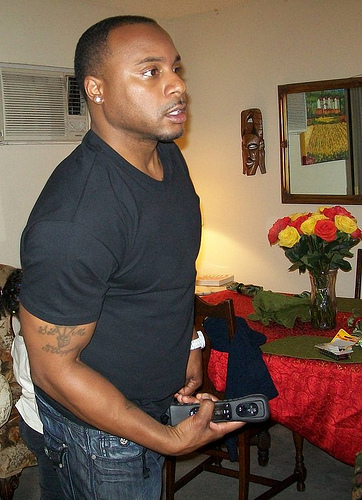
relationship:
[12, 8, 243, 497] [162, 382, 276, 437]
man holding wii remote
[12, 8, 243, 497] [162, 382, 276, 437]
man holding black wii remote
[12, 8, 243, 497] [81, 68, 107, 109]
man wearing earring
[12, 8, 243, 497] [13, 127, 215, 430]
man wearing shirt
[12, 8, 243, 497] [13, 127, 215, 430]
man wearing black shirt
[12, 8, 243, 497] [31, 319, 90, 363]
man with tatto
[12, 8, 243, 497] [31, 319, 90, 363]
man with tattoo on  arm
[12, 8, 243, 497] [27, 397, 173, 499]
man wearing jeans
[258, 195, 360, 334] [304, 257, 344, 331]
flowers in vase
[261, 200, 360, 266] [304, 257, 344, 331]
roses in glass vase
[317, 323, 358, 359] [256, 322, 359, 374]
batteries on green placema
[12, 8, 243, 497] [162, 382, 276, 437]
man playing wii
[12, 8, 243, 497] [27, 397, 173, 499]
man wearing denim jeans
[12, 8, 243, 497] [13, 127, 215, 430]
man wearing black tshirt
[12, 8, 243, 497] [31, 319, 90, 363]
man with tattoo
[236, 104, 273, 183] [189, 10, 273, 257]
mask on wall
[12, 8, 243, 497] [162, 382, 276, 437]
man holds remote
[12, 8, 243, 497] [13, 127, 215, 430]
man wears black shirt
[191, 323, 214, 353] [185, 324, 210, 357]
watch on wrist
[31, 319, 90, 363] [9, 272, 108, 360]
tattoo on bicep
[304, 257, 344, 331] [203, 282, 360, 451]
vase on table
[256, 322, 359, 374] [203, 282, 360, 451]
mat on table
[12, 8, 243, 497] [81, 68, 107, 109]
man has earing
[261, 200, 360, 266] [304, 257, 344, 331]
flowers are in vase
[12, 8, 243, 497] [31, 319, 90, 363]
man has tatto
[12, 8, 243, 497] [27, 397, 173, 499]
man has jeans on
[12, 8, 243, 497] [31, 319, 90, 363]
man has tattoo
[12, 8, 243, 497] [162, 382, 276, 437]
man playing video games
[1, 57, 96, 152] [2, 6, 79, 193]
conditioner unit in wall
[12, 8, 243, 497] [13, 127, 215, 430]
man wearing black t-shirt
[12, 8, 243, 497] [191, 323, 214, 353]
man wearing wristwatch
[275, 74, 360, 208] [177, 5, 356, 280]
mirror hanging on wall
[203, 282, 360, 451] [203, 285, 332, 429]
table covered with table cloth